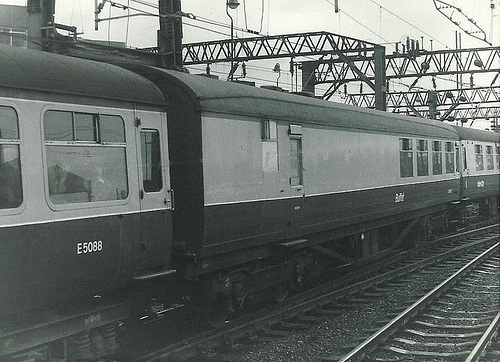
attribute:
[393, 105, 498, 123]
metal beam — over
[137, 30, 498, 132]
scaffolding — is metal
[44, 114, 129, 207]
window — is clear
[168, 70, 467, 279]
train truck — metallic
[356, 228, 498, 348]
track — metallic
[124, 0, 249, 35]
wire — is electrical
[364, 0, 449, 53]
wire — is electrical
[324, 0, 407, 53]
wire — is electrical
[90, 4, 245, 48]
wire — is electrical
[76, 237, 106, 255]
serial number — is white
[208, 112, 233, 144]
wall — grey, black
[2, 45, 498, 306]
train — is light, is dark, white, black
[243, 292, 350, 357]
train track — metallic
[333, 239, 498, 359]
tracks — metallic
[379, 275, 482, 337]
tracks — are silver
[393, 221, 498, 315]
tracks — are rusty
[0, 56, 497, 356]
train — black, white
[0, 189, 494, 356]
wheels — are black